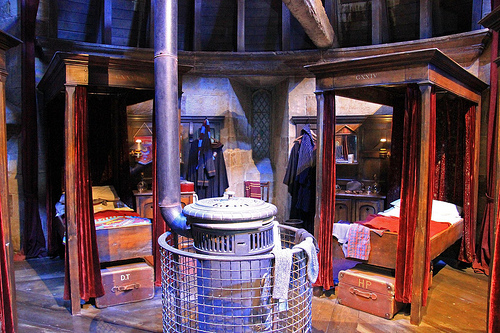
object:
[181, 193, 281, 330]
gas heater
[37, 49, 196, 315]
canopy post bed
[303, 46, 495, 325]
canopy post bed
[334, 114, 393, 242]
vanity station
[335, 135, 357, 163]
mirror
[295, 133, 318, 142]
coat rack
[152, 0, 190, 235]
heat pipe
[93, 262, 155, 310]
bed drawer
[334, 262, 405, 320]
bed drawer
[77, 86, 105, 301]
curtain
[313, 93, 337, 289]
curtain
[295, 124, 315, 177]
bathrobe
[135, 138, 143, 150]
candle lamp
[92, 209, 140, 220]
blanket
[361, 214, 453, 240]
blanket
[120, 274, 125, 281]
d.t.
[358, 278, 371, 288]
h.p.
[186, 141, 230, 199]
robe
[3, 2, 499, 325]
bedroom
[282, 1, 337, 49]
beam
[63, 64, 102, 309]
column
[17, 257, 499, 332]
floor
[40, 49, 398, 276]
wall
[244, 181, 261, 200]
scarf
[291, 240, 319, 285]
socks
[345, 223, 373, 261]
pajamas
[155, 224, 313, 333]
basket